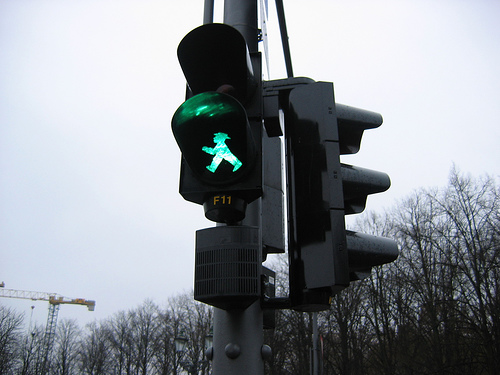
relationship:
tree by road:
[89, 320, 227, 368] [39, 324, 354, 374]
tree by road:
[2, 310, 31, 373] [133, 336, 484, 373]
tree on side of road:
[129, 298, 164, 373] [155, 348, 481, 372]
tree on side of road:
[426, 203, 494, 370] [185, 336, 484, 373]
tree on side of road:
[389, 223, 449, 351] [275, 349, 462, 373]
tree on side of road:
[423, 207, 480, 349] [301, 336, 480, 371]